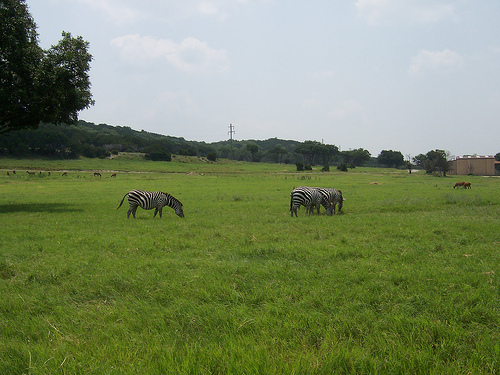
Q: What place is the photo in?
A: It is at the field.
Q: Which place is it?
A: It is a field.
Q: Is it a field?
A: Yes, it is a field.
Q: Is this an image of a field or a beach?
A: It is showing a field.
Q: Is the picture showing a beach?
A: No, the picture is showing a field.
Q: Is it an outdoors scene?
A: Yes, it is outdoors.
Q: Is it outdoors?
A: Yes, it is outdoors.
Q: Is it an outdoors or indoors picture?
A: It is outdoors.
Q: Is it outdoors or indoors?
A: It is outdoors.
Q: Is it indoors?
A: No, it is outdoors.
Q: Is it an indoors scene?
A: No, it is outdoors.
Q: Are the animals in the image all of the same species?
A: No, they are horses and zebras.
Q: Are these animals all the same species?
A: No, there are both horses and zebras.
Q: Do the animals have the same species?
A: No, there are both horses and zebras.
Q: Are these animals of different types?
A: Yes, they are horses and zebras.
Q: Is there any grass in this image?
A: Yes, there is grass.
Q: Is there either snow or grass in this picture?
A: Yes, there is grass.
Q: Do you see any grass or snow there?
A: Yes, there is grass.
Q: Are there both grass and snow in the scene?
A: No, there is grass but no snow.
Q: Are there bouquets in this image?
A: No, there are no bouquets.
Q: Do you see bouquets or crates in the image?
A: No, there are no bouquets or crates.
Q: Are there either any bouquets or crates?
A: No, there are no bouquets or crates.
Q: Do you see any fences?
A: No, there are no fences.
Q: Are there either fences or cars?
A: No, there are no fences or cars.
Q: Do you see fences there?
A: No, there are no fences.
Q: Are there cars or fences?
A: No, there are no fences or cars.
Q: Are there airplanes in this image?
A: No, there are no airplanes.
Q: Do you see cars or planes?
A: No, there are no planes or cars.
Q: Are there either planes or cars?
A: No, there are no planes or cars.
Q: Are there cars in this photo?
A: No, there are no cars.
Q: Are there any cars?
A: No, there are no cars.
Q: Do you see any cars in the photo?
A: No, there are no cars.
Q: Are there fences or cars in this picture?
A: No, there are no cars or fences.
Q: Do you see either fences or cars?
A: No, there are no cars or fences.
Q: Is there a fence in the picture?
A: No, there are no fences.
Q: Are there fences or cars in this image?
A: No, there are no fences or cars.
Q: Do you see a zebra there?
A: Yes, there is a zebra.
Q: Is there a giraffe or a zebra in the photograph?
A: Yes, there is a zebra.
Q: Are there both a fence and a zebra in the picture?
A: No, there is a zebra but no fences.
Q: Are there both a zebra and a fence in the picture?
A: No, there is a zebra but no fences.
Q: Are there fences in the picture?
A: No, there are no fences.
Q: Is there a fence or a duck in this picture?
A: No, there are no fences or ducks.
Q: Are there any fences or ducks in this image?
A: No, there are no fences or ducks.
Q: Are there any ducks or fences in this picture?
A: No, there are no fences or ducks.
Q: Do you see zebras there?
A: Yes, there is a zebra.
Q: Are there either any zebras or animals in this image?
A: Yes, there is a zebra.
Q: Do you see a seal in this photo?
A: No, there are no seals.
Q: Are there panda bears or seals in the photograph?
A: No, there are no seals or panda bears.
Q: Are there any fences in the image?
A: No, there are no fences.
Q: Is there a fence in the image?
A: No, there are no fences.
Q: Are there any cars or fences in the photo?
A: No, there are no fences or cars.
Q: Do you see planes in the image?
A: No, there are no planes.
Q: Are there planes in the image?
A: No, there are no planes.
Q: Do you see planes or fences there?
A: No, there are no planes or fences.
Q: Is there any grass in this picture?
A: Yes, there is grass.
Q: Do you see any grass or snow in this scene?
A: Yes, there is grass.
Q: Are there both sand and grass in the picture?
A: No, there is grass but no sand.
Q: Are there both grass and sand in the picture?
A: No, there is grass but no sand.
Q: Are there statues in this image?
A: No, there are no statues.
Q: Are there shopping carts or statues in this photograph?
A: No, there are no statues or shopping carts.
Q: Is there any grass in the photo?
A: Yes, there is grass.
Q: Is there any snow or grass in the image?
A: Yes, there is grass.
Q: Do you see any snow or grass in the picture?
A: Yes, there is grass.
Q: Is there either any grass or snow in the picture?
A: Yes, there is grass.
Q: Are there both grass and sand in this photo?
A: No, there is grass but no sand.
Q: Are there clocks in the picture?
A: No, there are no clocks.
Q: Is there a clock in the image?
A: No, there are no clocks.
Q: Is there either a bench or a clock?
A: No, there are no clocks or benches.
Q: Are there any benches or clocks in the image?
A: No, there are no clocks or benches.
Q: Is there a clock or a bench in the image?
A: No, there are no clocks or benches.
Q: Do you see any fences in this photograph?
A: No, there are no fences.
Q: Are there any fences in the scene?
A: No, there are no fences.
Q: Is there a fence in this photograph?
A: No, there are no fences.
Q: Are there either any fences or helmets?
A: No, there are no fences or helmets.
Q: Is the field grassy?
A: Yes, the field is grassy.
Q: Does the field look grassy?
A: Yes, the field is grassy.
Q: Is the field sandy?
A: No, the field is grassy.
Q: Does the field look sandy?
A: No, the field is grassy.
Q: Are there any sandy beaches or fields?
A: No, there is a field but it is grassy.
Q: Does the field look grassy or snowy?
A: The field is grassy.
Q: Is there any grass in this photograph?
A: Yes, there is grass.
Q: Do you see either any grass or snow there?
A: Yes, there is grass.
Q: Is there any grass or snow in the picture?
A: Yes, there is grass.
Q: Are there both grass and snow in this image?
A: No, there is grass but no snow.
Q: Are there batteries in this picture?
A: No, there are no batteries.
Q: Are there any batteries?
A: No, there are no batteries.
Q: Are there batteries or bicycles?
A: No, there are no batteries or bicycles.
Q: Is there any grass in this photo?
A: Yes, there is grass.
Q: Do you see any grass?
A: Yes, there is grass.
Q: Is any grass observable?
A: Yes, there is grass.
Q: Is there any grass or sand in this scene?
A: Yes, there is grass.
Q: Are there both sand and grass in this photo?
A: No, there is grass but no sand.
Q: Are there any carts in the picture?
A: No, there are no carts.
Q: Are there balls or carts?
A: No, there are no carts or balls.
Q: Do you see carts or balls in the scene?
A: No, there are no carts or balls.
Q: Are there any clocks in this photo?
A: No, there are no clocks.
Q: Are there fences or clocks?
A: No, there are no clocks or fences.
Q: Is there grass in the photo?
A: Yes, there is grass.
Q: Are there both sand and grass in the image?
A: No, there is grass but no sand.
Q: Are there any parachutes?
A: No, there are no parachutes.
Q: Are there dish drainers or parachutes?
A: No, there are no parachutes or dish drainers.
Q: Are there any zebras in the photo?
A: Yes, there is a zebra.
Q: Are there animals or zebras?
A: Yes, there is a zebra.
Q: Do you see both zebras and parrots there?
A: No, there is a zebra but no parrots.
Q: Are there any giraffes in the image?
A: No, there are no giraffes.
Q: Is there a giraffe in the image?
A: No, there are no giraffes.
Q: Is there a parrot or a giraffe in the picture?
A: No, there are no giraffes or parrots.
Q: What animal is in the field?
A: The animal is a zebra.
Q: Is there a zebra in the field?
A: Yes, there is a zebra in the field.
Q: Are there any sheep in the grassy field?
A: No, there is a zebra in the field.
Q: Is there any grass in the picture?
A: Yes, there is grass.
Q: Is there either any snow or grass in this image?
A: Yes, there is grass.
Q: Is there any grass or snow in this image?
A: Yes, there is grass.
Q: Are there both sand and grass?
A: No, there is grass but no sand.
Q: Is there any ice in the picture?
A: No, there is no ice.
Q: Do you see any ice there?
A: No, there is no ice.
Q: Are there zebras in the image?
A: Yes, there is a zebra.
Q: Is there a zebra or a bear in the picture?
A: Yes, there is a zebra.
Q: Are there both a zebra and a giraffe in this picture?
A: No, there is a zebra but no giraffes.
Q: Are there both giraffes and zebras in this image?
A: No, there is a zebra but no giraffes.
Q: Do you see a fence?
A: No, there are no fences.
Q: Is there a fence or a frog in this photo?
A: No, there are no fences or frogs.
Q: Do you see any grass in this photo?
A: Yes, there is grass.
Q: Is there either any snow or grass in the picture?
A: Yes, there is grass.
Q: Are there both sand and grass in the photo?
A: No, there is grass but no sand.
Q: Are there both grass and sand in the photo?
A: No, there is grass but no sand.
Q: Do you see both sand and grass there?
A: No, there is grass but no sand.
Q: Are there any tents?
A: No, there are no tents.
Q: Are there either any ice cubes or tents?
A: No, there are no tents or ice cubes.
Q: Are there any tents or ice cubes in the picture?
A: No, there are no tents or ice cubes.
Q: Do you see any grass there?
A: Yes, there is grass.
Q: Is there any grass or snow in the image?
A: Yes, there is grass.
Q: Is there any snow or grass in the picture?
A: Yes, there is grass.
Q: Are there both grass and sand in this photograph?
A: No, there is grass but no sand.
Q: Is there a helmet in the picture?
A: No, there are no helmets.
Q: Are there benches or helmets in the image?
A: No, there are no helmets or benches.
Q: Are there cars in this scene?
A: No, there are no cars.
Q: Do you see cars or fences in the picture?
A: No, there are no cars or fences.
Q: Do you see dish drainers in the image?
A: No, there are no dish drainers.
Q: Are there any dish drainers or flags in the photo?
A: No, there are no dish drainers or flags.